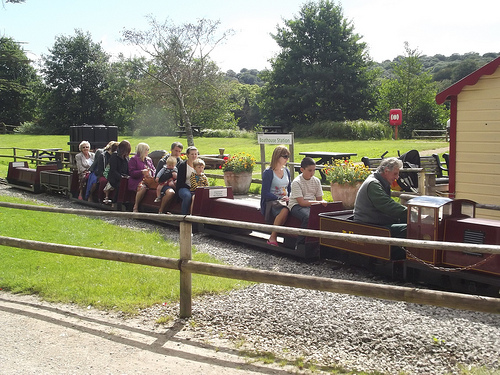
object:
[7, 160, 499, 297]
train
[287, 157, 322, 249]
passengers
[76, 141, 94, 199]
people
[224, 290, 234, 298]
rocks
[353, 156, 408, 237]
man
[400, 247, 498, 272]
chain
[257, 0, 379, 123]
tree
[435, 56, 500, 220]
building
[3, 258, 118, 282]
grass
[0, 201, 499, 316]
fence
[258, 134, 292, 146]
sign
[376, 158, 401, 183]
head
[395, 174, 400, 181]
nose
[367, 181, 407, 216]
arm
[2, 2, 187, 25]
sky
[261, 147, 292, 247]
woman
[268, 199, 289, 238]
leg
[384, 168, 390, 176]
ear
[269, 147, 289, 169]
head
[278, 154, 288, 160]
sunglasses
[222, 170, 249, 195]
planter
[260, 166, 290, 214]
sweater